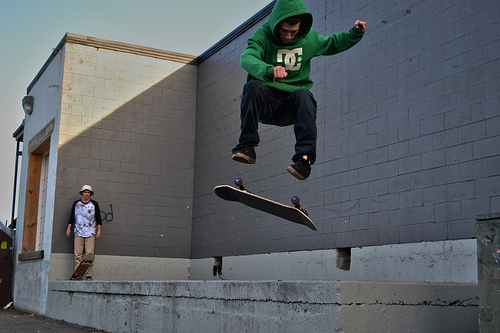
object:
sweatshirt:
[238, 0, 367, 94]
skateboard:
[212, 177, 318, 231]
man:
[65, 184, 102, 280]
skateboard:
[69, 253, 96, 280]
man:
[233, 0, 367, 181]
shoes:
[287, 156, 311, 180]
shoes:
[232, 146, 256, 164]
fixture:
[21, 95, 34, 115]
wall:
[12, 38, 63, 317]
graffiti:
[98, 204, 116, 224]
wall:
[54, 37, 198, 321]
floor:
[51, 274, 478, 310]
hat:
[78, 184, 94, 194]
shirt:
[68, 200, 102, 239]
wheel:
[234, 178, 243, 185]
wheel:
[290, 196, 301, 205]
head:
[79, 183, 94, 199]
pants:
[232, 80, 317, 159]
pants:
[74, 235, 95, 282]